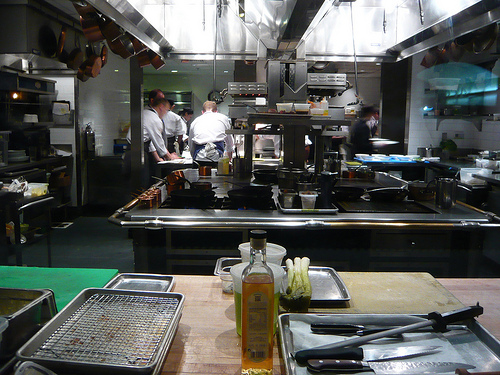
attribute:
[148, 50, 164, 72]
pot — copper, colored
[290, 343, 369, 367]
handle — brown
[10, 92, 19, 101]
light — orange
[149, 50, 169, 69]
hanging pot — copper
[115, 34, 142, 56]
pot — copper, Hanging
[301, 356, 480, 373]
knife — lying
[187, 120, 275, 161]
shirt — dark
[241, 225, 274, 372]
bottle — oil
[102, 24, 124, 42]
pot — color, copper, hanging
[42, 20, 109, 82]
pot — copper, colored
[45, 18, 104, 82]
pot — copper colored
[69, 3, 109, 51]
pot — copper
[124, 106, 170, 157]
shirt — white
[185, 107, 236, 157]
shirt — white